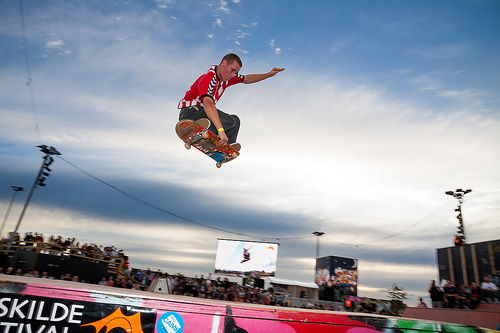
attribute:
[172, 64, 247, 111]
shirt — red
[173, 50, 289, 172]
skateboarder — in the air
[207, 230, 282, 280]
screen — displaying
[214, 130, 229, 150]
hand — gripping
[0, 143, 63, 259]
pole — electrical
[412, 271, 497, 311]
crowd — sitting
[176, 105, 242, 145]
pants — grey